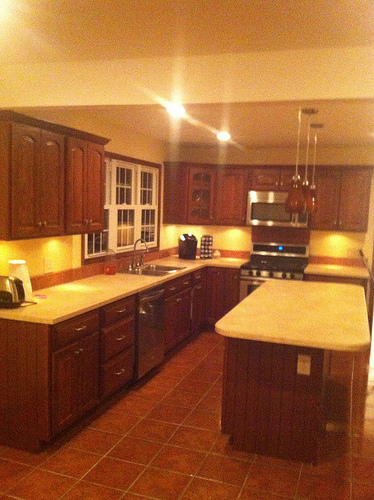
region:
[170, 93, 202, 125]
kitchen ceiling light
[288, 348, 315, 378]
outlet in the kitches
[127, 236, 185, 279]
kitchen sink with two sinks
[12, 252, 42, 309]
roll of paper towels on the counter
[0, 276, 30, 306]
toaster on the counter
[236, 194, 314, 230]
microwave above the stove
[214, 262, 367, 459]
island in the middle of the kitchen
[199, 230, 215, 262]
keurig coffee holdere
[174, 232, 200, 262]
single cup coffee maker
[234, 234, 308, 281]
stove and oven combo in kitchen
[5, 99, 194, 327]
the hanging cabinet is wooden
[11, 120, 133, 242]
the hanging cabinet is wooden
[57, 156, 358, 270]
the hanging cabinet is wooden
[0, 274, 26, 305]
stainless steel toaster on counter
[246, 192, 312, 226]
stainless steel microwave in cabinet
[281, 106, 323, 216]
lights hanging from ceiling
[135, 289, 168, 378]
stainless steel dishwasher inside counter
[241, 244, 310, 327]
stainless steel stove inside cabinet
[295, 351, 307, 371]
white outlet under counter on island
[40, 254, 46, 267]
white outlet on wall under cabinet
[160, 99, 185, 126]
light inside of ceiling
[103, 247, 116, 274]
dishwashing liquid bottle on counter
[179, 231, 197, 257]
black gadget on counter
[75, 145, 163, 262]
windows over kitchen sink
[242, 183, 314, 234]
microwave oven mounted over stove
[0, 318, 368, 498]
reddish kitchen floor tiles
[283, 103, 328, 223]
pendant lights over bar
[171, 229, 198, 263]
single serve coffee maker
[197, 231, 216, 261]
single serve pod holder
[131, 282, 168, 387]
stainless steel dishwasher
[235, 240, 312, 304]
stainless steel and black oven and stove top combination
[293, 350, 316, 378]
under counter electrical receptical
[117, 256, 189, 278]
stainless steel kitchen sink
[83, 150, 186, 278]
white windows above the stainless steel sink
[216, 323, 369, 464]
power outlet on the front part of the island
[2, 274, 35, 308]
silver and black toaster with a black cord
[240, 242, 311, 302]
silver and black stove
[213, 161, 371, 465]
brown and silver lights hanging above the island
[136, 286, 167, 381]
stainless steel dish washer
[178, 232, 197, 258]
black coffee maker in the corner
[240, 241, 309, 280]
blurry blue led clock above the stove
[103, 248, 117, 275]
plastic bottle with orange dish soap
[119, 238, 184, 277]
curved stainless steel faucet above the sink